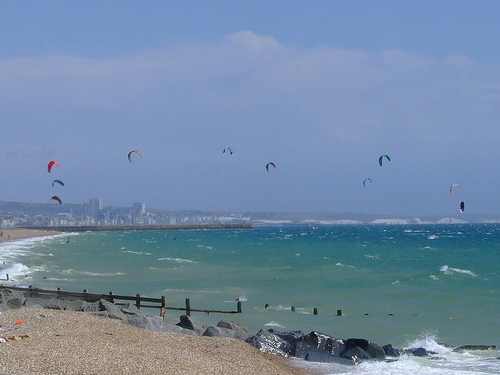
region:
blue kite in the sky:
[51, 173, 68, 192]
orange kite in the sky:
[122, 143, 145, 168]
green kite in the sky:
[373, 145, 394, 174]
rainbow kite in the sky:
[256, 158, 283, 179]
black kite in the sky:
[457, 191, 469, 215]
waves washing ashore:
[7, 230, 29, 280]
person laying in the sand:
[1, 326, 18, 346]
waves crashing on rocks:
[381, 330, 456, 371]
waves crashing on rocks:
[298, 323, 435, 373]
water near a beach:
[70, 227, 287, 371]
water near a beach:
[74, 205, 260, 327]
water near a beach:
[107, 188, 379, 360]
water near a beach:
[130, 202, 344, 321]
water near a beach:
[119, 236, 295, 333]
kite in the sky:
[39, 148, 69, 176]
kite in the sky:
[25, 190, 67, 215]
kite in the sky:
[40, 168, 77, 200]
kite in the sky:
[117, 142, 151, 170]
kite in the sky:
[206, 135, 246, 177]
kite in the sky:
[252, 148, 288, 199]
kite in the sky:
[348, 168, 381, 212]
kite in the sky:
[362, 151, 399, 173]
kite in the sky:
[431, 174, 463, 207]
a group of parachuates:
[38, 120, 453, 242]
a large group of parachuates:
[41, 125, 483, 260]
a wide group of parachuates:
[37, 96, 499, 251]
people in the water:
[170, 277, 492, 363]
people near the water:
[149, 252, 496, 372]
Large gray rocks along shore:
[1, 284, 496, 374]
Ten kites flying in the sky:
[2, 3, 498, 228]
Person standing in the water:
[149, 300, 172, 320]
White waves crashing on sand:
[1, 229, 78, 289]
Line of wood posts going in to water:
[3, 282, 426, 324]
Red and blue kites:
[43, 154, 65, 189]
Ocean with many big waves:
[3, 227, 498, 344]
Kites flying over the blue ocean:
[0, 4, 497, 344]